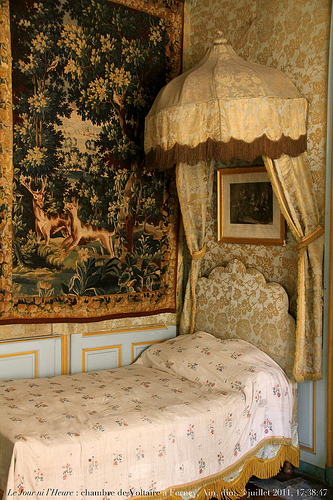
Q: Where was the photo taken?
A: It was taken at the bedroom.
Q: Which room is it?
A: It is a bedroom.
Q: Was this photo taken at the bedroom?
A: Yes, it was taken in the bedroom.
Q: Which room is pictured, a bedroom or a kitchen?
A: It is a bedroom.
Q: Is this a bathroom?
A: No, it is a bedroom.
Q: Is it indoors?
A: Yes, it is indoors.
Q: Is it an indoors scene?
A: Yes, it is indoors.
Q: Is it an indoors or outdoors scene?
A: It is indoors.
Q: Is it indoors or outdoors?
A: It is indoors.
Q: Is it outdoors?
A: No, it is indoors.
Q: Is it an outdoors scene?
A: No, it is indoors.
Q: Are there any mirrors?
A: No, there are no mirrors.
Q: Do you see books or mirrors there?
A: No, there are no mirrors or books.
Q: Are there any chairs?
A: No, there are no chairs.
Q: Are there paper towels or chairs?
A: No, there are no chairs or paper towels.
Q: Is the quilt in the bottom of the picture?
A: Yes, the quilt is in the bottom of the image.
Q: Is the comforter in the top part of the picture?
A: No, the comforter is in the bottom of the image.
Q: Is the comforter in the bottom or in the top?
A: The comforter is in the bottom of the image.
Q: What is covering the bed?
A: The comforter is covering the bed.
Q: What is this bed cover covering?
A: The bed cover is covering the bed.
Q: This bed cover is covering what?
A: The bed cover is covering the bed.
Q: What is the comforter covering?
A: The bed cover is covering the bed.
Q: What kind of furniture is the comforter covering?
A: The comforter is covering the bed.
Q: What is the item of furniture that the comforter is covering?
A: The piece of furniture is a bed.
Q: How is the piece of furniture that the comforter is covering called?
A: The piece of furniture is a bed.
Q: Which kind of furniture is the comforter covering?
A: The comforter is covering the bed.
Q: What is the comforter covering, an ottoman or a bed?
A: The comforter is covering a bed.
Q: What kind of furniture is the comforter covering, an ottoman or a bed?
A: The comforter is covering a bed.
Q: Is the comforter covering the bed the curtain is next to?
A: Yes, the comforter is covering the bed.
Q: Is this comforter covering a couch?
A: No, the comforter is covering the bed.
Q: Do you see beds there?
A: Yes, there is a bed.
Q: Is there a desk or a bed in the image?
A: Yes, there is a bed.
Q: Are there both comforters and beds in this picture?
A: Yes, there are both a bed and a comforter.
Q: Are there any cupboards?
A: No, there are no cupboards.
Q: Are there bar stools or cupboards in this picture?
A: No, there are no cupboards or bar stools.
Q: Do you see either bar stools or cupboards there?
A: No, there are no cupboards or bar stools.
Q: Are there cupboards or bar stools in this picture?
A: No, there are no cupboards or bar stools.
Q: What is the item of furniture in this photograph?
A: The piece of furniture is a bed.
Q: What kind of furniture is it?
A: The piece of furniture is a bed.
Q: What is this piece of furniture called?
A: This is a bed.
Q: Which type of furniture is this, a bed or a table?
A: This is a bed.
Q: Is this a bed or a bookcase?
A: This is a bed.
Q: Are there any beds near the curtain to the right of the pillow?
A: Yes, there is a bed near the curtain.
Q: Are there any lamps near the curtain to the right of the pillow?
A: No, there is a bed near the curtain.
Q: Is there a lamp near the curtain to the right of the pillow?
A: No, there is a bed near the curtain.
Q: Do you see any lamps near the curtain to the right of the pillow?
A: No, there is a bed near the curtain.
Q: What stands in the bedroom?
A: The bed stands in the bedroom.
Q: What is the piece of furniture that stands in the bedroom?
A: The piece of furniture is a bed.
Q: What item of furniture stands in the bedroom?
A: The piece of furniture is a bed.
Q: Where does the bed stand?
A: The bed stands in the bedroom.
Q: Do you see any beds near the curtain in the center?
A: Yes, there is a bed near the curtain.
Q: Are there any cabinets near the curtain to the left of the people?
A: No, there is a bed near the curtain.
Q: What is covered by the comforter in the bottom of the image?
A: The bed is covered by the comforter.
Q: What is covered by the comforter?
A: The bed is covered by the comforter.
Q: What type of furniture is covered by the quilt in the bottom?
A: The piece of furniture is a bed.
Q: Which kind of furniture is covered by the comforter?
A: The piece of furniture is a bed.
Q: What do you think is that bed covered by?
A: The bed is covered by the quilt.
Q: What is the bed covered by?
A: The bed is covered by the quilt.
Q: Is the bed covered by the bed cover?
A: Yes, the bed is covered by the bed cover.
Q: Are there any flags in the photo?
A: No, there are no flags.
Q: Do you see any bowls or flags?
A: No, there are no flags or bowls.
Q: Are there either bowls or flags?
A: No, there are no flags or bowls.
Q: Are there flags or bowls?
A: No, there are no flags or bowls.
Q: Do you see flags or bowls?
A: No, there are no flags or bowls.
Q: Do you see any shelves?
A: No, there are no shelves.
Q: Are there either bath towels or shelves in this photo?
A: No, there are no shelves or bath towels.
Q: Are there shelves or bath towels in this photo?
A: No, there are no shelves or bath towels.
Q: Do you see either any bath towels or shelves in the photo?
A: No, there are no shelves or bath towels.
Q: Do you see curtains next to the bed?
A: Yes, there is a curtain next to the bed.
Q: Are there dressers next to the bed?
A: No, there is a curtain next to the bed.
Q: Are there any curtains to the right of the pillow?
A: Yes, there is a curtain to the right of the pillow.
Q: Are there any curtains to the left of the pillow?
A: No, the curtain is to the right of the pillow.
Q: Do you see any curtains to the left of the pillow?
A: No, the curtain is to the right of the pillow.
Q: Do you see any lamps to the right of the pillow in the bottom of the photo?
A: No, there is a curtain to the right of the pillow.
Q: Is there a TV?
A: No, there are no televisions.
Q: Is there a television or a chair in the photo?
A: No, there are no televisions or chairs.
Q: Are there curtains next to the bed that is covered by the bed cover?
A: Yes, there is a curtain next to the bed.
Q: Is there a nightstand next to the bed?
A: No, there is a curtain next to the bed.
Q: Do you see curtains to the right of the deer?
A: Yes, there is a curtain to the right of the deer.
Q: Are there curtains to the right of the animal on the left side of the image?
A: Yes, there is a curtain to the right of the deer.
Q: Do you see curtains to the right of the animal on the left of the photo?
A: Yes, there is a curtain to the right of the deer.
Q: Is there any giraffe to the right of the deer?
A: No, there is a curtain to the right of the deer.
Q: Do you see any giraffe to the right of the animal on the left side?
A: No, there is a curtain to the right of the deer.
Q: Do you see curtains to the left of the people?
A: Yes, there is a curtain to the left of the people.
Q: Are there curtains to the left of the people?
A: Yes, there is a curtain to the left of the people.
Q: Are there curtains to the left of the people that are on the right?
A: Yes, there is a curtain to the left of the people.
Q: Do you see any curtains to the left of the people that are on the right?
A: Yes, there is a curtain to the left of the people.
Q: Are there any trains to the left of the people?
A: No, there is a curtain to the left of the people.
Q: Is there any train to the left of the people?
A: No, there is a curtain to the left of the people.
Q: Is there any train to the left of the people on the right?
A: No, there is a curtain to the left of the people.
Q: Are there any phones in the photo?
A: No, there are no phones.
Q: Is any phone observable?
A: No, there are no phones.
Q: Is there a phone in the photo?
A: No, there are no phones.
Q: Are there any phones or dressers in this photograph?
A: No, there are no phones or dressers.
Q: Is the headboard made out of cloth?
A: Yes, the headboard is made of cloth.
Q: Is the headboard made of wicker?
A: No, the headboard is made of cloth.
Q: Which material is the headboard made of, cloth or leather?
A: The headboard is made of cloth.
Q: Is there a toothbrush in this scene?
A: No, there are no toothbrushes.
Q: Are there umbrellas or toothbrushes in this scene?
A: No, there are no toothbrushes or umbrellas.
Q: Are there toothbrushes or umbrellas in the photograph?
A: No, there are no toothbrushes or umbrellas.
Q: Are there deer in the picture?
A: Yes, there is a deer.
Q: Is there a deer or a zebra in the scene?
A: Yes, there is a deer.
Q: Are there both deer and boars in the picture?
A: No, there is a deer but no boars.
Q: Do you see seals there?
A: No, there are no seals.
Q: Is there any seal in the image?
A: No, there are no seals.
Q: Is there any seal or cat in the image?
A: No, there are no seals or cats.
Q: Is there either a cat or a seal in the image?
A: No, there are no seals or cats.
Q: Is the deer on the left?
A: Yes, the deer is on the left of the image.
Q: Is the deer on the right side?
A: No, the deer is on the left of the image.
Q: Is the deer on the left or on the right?
A: The deer is on the left of the image.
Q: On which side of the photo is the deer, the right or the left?
A: The deer is on the left of the image.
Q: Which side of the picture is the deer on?
A: The deer is on the left of the image.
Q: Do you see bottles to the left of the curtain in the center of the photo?
A: No, there is a deer to the left of the curtain.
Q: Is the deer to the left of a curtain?
A: Yes, the deer is to the left of a curtain.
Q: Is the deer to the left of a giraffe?
A: No, the deer is to the left of a curtain.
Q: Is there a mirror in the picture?
A: No, there are no mirrors.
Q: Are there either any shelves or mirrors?
A: No, there are no mirrors or shelves.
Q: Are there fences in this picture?
A: No, there are no fences.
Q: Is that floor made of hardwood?
A: Yes, the floor is made of hardwood.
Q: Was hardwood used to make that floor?
A: Yes, the floor is made of hardwood.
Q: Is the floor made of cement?
A: No, the floor is made of hardwood.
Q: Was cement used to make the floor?
A: No, the floor is made of hardwood.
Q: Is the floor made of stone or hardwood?
A: The floor is made of hardwood.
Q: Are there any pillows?
A: Yes, there is a pillow.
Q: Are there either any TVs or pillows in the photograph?
A: Yes, there is a pillow.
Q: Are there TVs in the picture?
A: No, there are no tvs.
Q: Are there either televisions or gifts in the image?
A: No, there are no televisions or gifts.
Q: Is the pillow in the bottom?
A: Yes, the pillow is in the bottom of the image.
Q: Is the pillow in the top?
A: No, the pillow is in the bottom of the image.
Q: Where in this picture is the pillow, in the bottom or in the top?
A: The pillow is in the bottom of the image.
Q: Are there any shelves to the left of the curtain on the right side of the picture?
A: No, there is a pillow to the left of the curtain.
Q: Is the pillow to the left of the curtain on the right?
A: Yes, the pillow is to the left of the curtain.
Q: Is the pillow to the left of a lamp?
A: No, the pillow is to the left of the curtain.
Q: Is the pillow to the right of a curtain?
A: No, the pillow is to the left of a curtain.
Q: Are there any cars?
A: No, there are no cars.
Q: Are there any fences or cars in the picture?
A: No, there are no cars or fences.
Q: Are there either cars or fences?
A: No, there are no cars or fences.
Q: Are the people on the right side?
A: Yes, the people are on the right of the image.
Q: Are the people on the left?
A: No, the people are on the right of the image.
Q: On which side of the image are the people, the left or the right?
A: The people are on the right of the image.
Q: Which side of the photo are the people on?
A: The people are on the right of the image.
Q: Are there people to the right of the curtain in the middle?
A: Yes, there are people to the right of the curtain.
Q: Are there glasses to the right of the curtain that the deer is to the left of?
A: No, there are people to the right of the curtain.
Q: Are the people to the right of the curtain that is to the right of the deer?
A: Yes, the people are to the right of the curtain.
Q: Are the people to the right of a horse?
A: No, the people are to the right of the curtain.